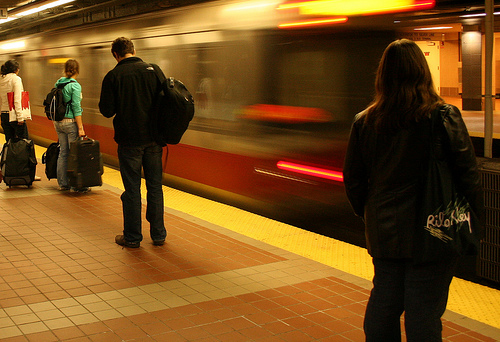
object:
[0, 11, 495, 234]
train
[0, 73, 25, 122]
jacket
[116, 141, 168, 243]
pants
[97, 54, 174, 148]
clothes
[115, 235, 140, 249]
tennis shoes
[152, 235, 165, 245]
tennis shoes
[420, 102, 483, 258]
bag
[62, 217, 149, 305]
tiles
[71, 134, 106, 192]
suitcase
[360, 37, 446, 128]
hair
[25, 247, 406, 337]
platform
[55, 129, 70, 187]
leg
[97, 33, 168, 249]
boy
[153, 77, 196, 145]
backpack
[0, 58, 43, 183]
person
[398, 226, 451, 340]
leg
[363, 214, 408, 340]
leg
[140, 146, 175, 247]
leg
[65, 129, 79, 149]
leg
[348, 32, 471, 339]
leg person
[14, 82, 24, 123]
arm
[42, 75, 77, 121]
suitcase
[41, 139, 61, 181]
suitcase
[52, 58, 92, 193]
girl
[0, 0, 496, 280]
bus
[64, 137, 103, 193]
luggage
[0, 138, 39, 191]
suitcase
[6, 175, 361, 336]
sidewalk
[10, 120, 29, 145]
leg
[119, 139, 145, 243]
leg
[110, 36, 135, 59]
brown hair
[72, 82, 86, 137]
arm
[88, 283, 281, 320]
pavement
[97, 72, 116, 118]
arm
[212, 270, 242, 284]
paint